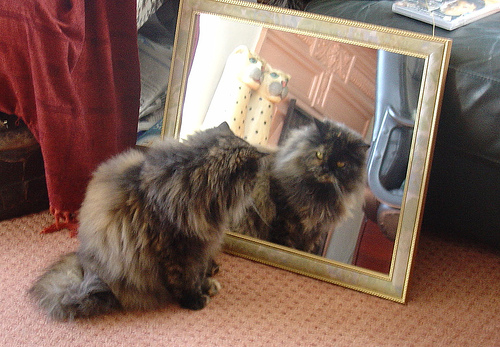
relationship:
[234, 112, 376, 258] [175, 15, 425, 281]
reflection inside of mirror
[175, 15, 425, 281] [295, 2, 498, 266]
mirror against couch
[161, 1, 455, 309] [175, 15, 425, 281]
frame around mirror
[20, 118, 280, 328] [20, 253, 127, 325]
cat has tail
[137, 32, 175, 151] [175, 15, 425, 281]
newspaper beside mirror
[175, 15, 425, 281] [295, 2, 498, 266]
mirror leaning against couch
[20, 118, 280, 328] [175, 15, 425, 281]
cat looking in mirror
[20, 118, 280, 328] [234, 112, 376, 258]
cat has reflection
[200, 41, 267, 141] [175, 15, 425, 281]
statue inside of mirror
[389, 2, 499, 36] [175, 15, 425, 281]
picture behind mirror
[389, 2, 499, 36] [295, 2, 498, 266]
picture on top of couch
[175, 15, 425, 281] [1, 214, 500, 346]
mirror on carpet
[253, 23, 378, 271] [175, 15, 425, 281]
mantle inside of mirror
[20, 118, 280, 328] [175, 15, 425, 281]
cat staring into mirror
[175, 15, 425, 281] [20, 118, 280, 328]
mirror reflecting cat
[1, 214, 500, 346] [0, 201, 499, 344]
carpet on floor